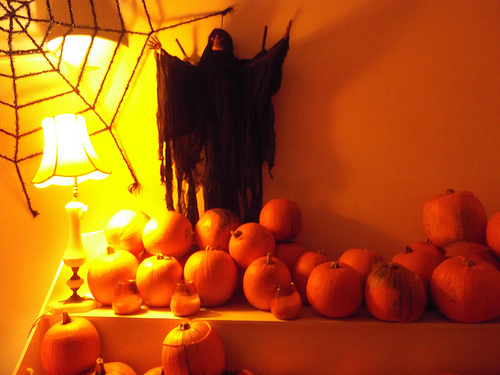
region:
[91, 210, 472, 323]
Various pumpkins sit on the top of the counter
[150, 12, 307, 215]
A skeleton with a black cloak outstretches its arms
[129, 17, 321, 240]
The skeleton rises above the pumpkins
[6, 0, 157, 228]
A black spider web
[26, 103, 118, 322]
A narrow, white lamp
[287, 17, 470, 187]
The wall is orange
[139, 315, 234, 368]
The top of the pumpkin is cut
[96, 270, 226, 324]
Orange candles line the counter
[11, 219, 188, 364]
A white board keeps the pumpkins from falling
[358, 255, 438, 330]
The pumpkin has green coloring over half of it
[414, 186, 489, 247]
orange pumpkin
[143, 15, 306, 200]
white skeleton dressed in black flowing garment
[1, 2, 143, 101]
black spiderweb decoration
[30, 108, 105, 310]
lit table lamp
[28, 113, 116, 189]
yellow lamp shade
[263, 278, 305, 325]
unlit white candle in glass jar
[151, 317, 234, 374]
orange pumpkin with top carved off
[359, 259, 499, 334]
two orange pumpkins next to each other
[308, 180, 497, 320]
ten orange pumpkins lined up against a tan wall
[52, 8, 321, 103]
Halloween decorations hanging on a wall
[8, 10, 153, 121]
a homemade spider's web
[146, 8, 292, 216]
a skeleton dressed in a black dress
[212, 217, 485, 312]
lots of orange pumpkins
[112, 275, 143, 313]
a small candle that looks burnt out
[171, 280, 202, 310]
a small candle with a blackened top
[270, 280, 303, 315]
a small candle full of wax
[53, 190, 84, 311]
a tall candlestick lamp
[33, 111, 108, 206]
the lampshade glows from the light on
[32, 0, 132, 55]
here's another light that's on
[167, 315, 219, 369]
this pumpkin has been cut open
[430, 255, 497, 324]
a round orange fruit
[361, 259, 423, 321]
a round orange fruit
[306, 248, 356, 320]
a round orange fruit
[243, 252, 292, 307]
a round orange fruit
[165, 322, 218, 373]
a round orange fruit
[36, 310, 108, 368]
a round orange fruit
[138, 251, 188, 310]
a round orange fruit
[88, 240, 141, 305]
a round orange fruit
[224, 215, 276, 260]
a round orange fruit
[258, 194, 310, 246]
a round orange fruit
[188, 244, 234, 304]
a round fruit-like object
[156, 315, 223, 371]
a round fruit-like object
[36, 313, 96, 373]
a round fruit-like object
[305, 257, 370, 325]
a round fruit-like object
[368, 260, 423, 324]
a round fruit-like object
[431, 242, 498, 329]
a round fruit-like object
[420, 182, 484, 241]
a round fruit-like object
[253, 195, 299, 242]
a round fruit-like object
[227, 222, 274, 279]
a round fruit-like object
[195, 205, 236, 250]
a round fruit-like object